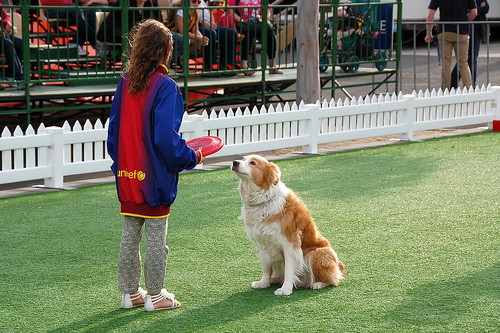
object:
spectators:
[193, 0, 241, 76]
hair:
[125, 16, 173, 95]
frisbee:
[186, 136, 224, 158]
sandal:
[142, 288, 182, 312]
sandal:
[119, 285, 149, 309]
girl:
[106, 17, 201, 312]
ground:
[0, 42, 499, 331]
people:
[226, 0, 285, 77]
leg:
[273, 234, 302, 296]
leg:
[251, 244, 274, 289]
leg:
[311, 248, 343, 291]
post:
[294, 0, 321, 110]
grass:
[0, 131, 499, 333]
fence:
[0, 82, 500, 192]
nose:
[232, 159, 239, 166]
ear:
[264, 161, 281, 186]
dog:
[231, 154, 344, 296]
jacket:
[104, 60, 204, 219]